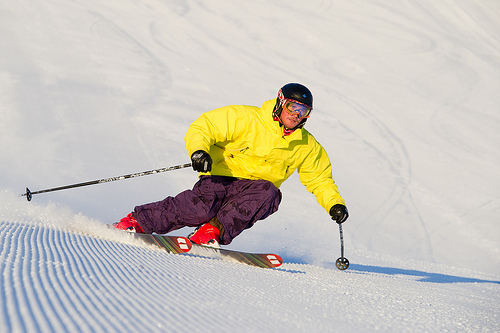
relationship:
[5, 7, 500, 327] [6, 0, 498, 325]
ground covered in snow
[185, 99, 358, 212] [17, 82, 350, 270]
coat on man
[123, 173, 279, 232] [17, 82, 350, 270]
pants on man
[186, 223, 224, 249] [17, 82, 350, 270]
boots on man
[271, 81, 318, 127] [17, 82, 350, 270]
helmet on man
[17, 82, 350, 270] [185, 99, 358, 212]
man in coat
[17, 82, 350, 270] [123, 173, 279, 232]
man in pants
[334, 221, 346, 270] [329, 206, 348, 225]
pole in hand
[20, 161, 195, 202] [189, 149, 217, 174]
pole in hand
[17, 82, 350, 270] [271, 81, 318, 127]
man wearing helmet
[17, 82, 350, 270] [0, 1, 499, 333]
man on hillside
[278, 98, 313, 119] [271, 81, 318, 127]
goggles under helmet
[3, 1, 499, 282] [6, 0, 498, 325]
hillside covered in snow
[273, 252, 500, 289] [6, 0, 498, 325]
shadow in snow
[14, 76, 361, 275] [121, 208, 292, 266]
downhill skier making turn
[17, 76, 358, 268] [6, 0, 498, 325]
man in snow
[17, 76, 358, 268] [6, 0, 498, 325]
man skiing in snow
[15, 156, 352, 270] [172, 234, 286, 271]
skis with tips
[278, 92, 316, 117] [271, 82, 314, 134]
ski goggles on head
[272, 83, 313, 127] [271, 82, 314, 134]
helmet on head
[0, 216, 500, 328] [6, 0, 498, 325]
ripples in snow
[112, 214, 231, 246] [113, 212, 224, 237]
boots on feet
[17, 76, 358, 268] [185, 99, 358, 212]
person wearing coat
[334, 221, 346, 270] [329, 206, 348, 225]
pole on hand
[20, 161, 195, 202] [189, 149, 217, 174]
pole on hand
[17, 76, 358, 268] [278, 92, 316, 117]
man wears goggles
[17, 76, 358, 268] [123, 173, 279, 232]
man has pants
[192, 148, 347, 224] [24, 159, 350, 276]
gloves holding poles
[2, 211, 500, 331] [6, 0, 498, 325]
marks in snow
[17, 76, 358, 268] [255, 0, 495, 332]
man inclined right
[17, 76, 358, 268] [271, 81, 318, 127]
man wears helmet